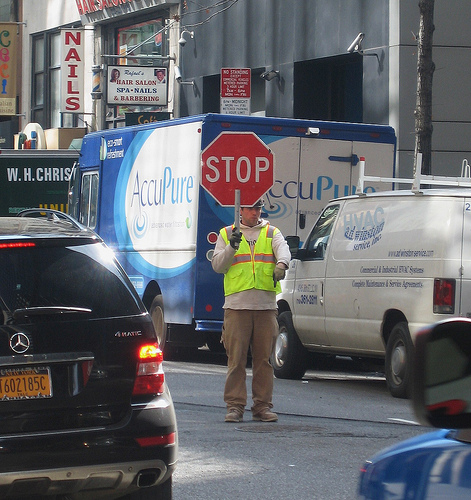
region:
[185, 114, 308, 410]
a man with STOP sign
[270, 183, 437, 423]
the van is white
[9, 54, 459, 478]
a street full of traffic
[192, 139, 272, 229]
a stop sign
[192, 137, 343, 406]
a worker directing traffic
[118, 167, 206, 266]
a truck with a logo on the side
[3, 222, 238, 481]
a black mercedes suv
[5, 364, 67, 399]
a new york license plate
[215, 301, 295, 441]
a pair of khaki pants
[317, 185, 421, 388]
a white paneled van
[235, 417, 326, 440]
a man hole cover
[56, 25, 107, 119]
a sign for a nail salon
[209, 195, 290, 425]
Man holding a stop sign.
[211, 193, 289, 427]
Man wearing a bright colored vest.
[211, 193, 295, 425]
Man wearing a pair of pants.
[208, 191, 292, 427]
Man wearing a pair of shoes.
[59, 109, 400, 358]
Blue and white van.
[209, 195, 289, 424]
Man holding a red and white sign.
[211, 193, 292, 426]
Man wearing a sweatshirt.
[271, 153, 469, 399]
White van with a rack on top.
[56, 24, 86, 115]
Sign that says nails.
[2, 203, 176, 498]
Black vehicle with a yellow license plate.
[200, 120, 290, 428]
a man holding a stop sign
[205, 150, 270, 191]
white lettering on a red sign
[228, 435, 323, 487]
black asphalt surface of the road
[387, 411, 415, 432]
white line painted on the road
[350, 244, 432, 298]
blue lettering on the side of a white van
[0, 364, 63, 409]
yellow license plate on a black SUV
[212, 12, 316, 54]
grey concrete wall of a building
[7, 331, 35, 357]
grey metal logo on the black SUV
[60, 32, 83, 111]
red lettering on a white sign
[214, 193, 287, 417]
a man wearing a yellow vest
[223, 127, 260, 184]
There is a Stop sign that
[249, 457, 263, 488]
There is a patch of black asphalt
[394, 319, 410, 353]
There are large, black tires here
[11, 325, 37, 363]
This care is Mercedes-Benz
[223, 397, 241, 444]
There are larg, brown boots here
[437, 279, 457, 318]
There is a red tail light here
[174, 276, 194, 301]
There is a blue color on this truck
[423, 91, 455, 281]
There is a dark brown trunk here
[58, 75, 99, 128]
This place says "Nails"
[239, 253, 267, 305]
This man has a very bright vest